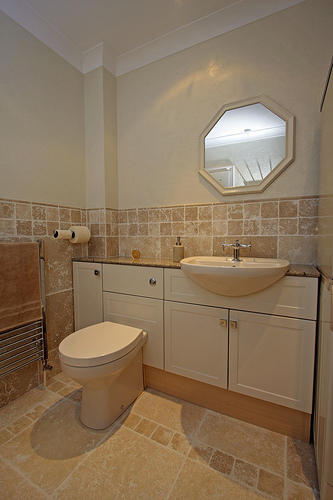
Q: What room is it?
A: It is a bathroom.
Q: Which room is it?
A: It is a bathroom.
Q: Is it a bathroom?
A: Yes, it is a bathroom.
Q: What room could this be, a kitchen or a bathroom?
A: It is a bathroom.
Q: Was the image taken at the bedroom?
A: No, the picture was taken in the bathroom.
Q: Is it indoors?
A: Yes, it is indoors.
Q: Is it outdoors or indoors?
A: It is indoors.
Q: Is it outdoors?
A: No, it is indoors.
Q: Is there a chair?
A: No, there are no chairs.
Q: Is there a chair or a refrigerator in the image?
A: No, there are no chairs or refrigerators.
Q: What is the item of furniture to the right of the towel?
A: The piece of furniture is a drawer.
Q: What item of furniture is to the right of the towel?
A: The piece of furniture is a drawer.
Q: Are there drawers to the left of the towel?
A: No, the drawer is to the right of the towel.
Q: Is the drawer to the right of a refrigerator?
A: No, the drawer is to the right of the towel.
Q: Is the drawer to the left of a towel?
A: No, the drawer is to the right of a towel.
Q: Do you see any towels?
A: Yes, there is a towel.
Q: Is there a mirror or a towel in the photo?
A: Yes, there is a towel.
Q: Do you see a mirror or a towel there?
A: Yes, there is a towel.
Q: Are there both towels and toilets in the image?
A: Yes, there are both a towel and a toilet.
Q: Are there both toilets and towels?
A: Yes, there are both a towel and a toilet.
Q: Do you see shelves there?
A: No, there are no shelves.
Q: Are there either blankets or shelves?
A: No, there are no shelves or blankets.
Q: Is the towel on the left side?
A: Yes, the towel is on the left of the image.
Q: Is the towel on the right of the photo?
A: No, the towel is on the left of the image.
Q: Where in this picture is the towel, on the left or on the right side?
A: The towel is on the left of the image.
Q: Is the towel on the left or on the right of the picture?
A: The towel is on the left of the image.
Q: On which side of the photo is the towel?
A: The towel is on the left of the image.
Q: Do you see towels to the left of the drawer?
A: Yes, there is a towel to the left of the drawer.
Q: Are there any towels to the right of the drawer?
A: No, the towel is to the left of the drawer.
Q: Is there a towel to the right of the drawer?
A: No, the towel is to the left of the drawer.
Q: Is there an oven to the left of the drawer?
A: No, there is a towel to the left of the drawer.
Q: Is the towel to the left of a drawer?
A: Yes, the towel is to the left of a drawer.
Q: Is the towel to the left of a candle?
A: No, the towel is to the left of a drawer.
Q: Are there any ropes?
A: No, there are no ropes.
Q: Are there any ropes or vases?
A: No, there are no ropes or vases.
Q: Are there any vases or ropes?
A: No, there are no ropes or vases.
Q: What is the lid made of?
A: The lid is made of plastic.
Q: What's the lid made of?
A: The lid is made of plastic.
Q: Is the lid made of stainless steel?
A: No, the lid is made of plastic.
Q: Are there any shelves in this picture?
A: No, there are no shelves.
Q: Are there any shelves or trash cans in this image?
A: No, there are no shelves or trash cans.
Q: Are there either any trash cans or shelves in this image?
A: No, there are no shelves or trash cans.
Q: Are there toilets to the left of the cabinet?
A: Yes, there is a toilet to the left of the cabinet.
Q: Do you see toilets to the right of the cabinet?
A: No, the toilet is to the left of the cabinet.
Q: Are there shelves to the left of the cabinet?
A: No, there is a toilet to the left of the cabinet.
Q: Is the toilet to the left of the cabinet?
A: Yes, the toilet is to the left of the cabinet.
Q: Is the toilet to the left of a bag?
A: No, the toilet is to the left of the cabinet.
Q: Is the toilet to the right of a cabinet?
A: No, the toilet is to the left of a cabinet.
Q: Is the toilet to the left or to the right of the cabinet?
A: The toilet is to the left of the cabinet.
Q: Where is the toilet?
A: The toilet is in the bathroom.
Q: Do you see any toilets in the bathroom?
A: Yes, there is a toilet in the bathroom.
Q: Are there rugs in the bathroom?
A: No, there is a toilet in the bathroom.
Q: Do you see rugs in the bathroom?
A: No, there is a toilet in the bathroom.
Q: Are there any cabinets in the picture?
A: Yes, there is a cabinet.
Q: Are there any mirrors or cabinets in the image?
A: Yes, there is a cabinet.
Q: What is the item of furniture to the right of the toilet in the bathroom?
A: The piece of furniture is a cabinet.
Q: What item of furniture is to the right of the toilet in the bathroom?
A: The piece of furniture is a cabinet.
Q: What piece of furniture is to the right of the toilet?
A: The piece of furniture is a cabinet.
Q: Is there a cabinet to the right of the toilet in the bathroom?
A: Yes, there is a cabinet to the right of the toilet.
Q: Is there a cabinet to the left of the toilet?
A: No, the cabinet is to the right of the toilet.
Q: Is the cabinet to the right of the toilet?
A: Yes, the cabinet is to the right of the toilet.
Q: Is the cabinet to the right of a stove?
A: No, the cabinet is to the right of the toilet.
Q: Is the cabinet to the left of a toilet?
A: No, the cabinet is to the right of a toilet.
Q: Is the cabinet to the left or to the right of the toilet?
A: The cabinet is to the right of the toilet.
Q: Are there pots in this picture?
A: No, there are no pots.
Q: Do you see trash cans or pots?
A: No, there are no pots or trash cans.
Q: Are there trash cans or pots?
A: No, there are no pots or trash cans.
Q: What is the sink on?
A: The sink is on the counter.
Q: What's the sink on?
A: The sink is on the counter.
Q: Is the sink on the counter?
A: Yes, the sink is on the counter.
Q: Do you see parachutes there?
A: No, there are no parachutes.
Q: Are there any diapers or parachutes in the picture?
A: No, there are no parachutes or diapers.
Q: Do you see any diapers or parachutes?
A: No, there are no parachutes or diapers.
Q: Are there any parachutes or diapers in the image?
A: No, there are no parachutes or diapers.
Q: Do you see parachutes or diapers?
A: No, there are no parachutes or diapers.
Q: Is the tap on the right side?
A: Yes, the tap is on the right of the image.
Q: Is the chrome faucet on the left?
A: No, the faucet is on the right of the image.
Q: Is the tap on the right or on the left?
A: The tap is on the right of the image.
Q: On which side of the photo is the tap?
A: The tap is on the right of the image.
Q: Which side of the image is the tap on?
A: The tap is on the right of the image.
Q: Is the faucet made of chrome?
A: Yes, the faucet is made of chrome.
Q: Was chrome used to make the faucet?
A: Yes, the faucet is made of chrome.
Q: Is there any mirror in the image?
A: Yes, there is a mirror.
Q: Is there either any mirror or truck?
A: Yes, there is a mirror.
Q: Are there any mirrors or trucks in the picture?
A: Yes, there is a mirror.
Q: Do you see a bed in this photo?
A: No, there are no beds.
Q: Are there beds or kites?
A: No, there are no beds or kites.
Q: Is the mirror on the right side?
A: Yes, the mirror is on the right of the image.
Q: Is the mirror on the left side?
A: No, the mirror is on the right of the image.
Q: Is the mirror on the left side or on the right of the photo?
A: The mirror is on the right of the image.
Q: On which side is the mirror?
A: The mirror is on the right of the image.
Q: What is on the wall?
A: The mirror is on the wall.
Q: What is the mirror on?
A: The mirror is on the wall.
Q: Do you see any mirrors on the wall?
A: Yes, there is a mirror on the wall.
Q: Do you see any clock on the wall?
A: No, there is a mirror on the wall.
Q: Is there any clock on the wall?
A: No, there is a mirror on the wall.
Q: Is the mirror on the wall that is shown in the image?
A: Yes, the mirror is on the wall.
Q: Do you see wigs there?
A: No, there are no wigs.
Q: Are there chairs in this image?
A: No, there are no chairs.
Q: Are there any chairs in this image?
A: No, there are no chairs.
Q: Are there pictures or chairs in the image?
A: No, there are no chairs or pictures.